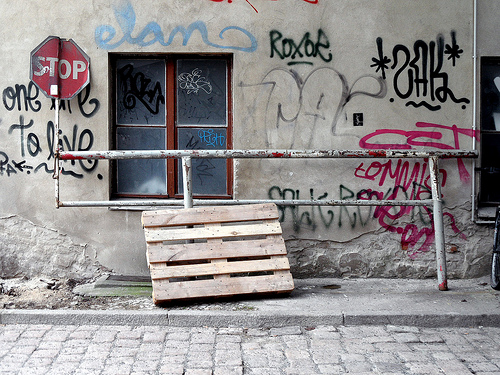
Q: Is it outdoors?
A: Yes, it is outdoors.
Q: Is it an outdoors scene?
A: Yes, it is outdoors.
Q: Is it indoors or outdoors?
A: It is outdoors.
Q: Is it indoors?
A: No, it is outdoors.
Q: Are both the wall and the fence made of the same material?
A: No, the wall is made of concrete and the fence is made of metal.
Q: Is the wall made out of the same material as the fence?
A: No, the wall is made of concrete and the fence is made of metal.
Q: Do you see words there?
A: Yes, there are words.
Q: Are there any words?
A: Yes, there are words.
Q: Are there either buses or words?
A: Yes, there are words.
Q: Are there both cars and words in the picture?
A: No, there are words but no cars.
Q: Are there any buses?
A: No, there are no buses.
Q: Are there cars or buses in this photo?
A: No, there are no buses or cars.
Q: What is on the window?
A: The words are on the window.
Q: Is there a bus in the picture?
A: No, there are no buses.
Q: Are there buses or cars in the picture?
A: No, there are no buses or cars.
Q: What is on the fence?
A: The sign is on the fence.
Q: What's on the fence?
A: The sign is on the fence.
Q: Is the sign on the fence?
A: Yes, the sign is on the fence.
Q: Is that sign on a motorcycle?
A: No, the sign is on the fence.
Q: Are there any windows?
A: Yes, there is a window.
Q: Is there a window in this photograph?
A: Yes, there is a window.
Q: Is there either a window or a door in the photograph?
A: Yes, there is a window.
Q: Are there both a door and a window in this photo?
A: No, there is a window but no doors.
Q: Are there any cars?
A: No, there are no cars.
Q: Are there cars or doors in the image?
A: No, there are no cars or doors.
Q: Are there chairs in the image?
A: No, there are no chairs.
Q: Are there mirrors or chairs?
A: No, there are no chairs or mirrors.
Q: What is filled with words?
A: The wall is filled with words.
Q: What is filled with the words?
A: The wall is filled with words.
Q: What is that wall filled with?
A: The wall is filled with words.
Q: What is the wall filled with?
A: The wall is filled with words.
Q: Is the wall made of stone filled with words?
A: Yes, the wall is filled with words.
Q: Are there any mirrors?
A: No, there are no mirrors.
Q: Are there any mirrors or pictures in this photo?
A: No, there are no mirrors or pictures.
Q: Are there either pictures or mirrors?
A: No, there are no mirrors or pictures.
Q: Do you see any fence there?
A: Yes, there is a fence.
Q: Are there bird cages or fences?
A: Yes, there is a fence.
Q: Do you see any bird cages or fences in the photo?
A: Yes, there is a fence.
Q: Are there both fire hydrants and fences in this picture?
A: No, there is a fence but no fire hydrants.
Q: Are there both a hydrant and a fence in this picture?
A: No, there is a fence but no fire hydrants.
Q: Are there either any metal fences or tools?
A: Yes, there is a metal fence.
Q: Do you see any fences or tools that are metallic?
A: Yes, the fence is metallic.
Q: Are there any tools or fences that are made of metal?
A: Yes, the fence is made of metal.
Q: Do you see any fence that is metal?
A: Yes, there is a metal fence.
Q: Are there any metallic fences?
A: Yes, there is a metal fence.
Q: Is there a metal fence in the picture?
A: Yes, there is a metal fence.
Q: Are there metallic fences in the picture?
A: Yes, there is a metal fence.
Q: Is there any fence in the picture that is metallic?
A: Yes, there is a fence that is metallic.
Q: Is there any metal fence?
A: Yes, there is a fence that is made of metal.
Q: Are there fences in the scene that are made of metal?
A: Yes, there is a fence that is made of metal.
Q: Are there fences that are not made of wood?
A: Yes, there is a fence that is made of metal.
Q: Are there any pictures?
A: No, there are no pictures.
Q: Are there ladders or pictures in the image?
A: No, there are no pictures or ladders.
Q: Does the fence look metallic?
A: Yes, the fence is metallic.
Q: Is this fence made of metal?
A: Yes, the fence is made of metal.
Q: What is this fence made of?
A: The fence is made of metal.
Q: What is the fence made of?
A: The fence is made of metal.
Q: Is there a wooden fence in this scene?
A: No, there is a fence but it is metallic.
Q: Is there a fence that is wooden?
A: No, there is a fence but it is metallic.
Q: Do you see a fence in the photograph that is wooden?
A: No, there is a fence but it is metallic.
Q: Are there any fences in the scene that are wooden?
A: No, there is a fence but it is metallic.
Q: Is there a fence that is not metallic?
A: No, there is a fence but it is metallic.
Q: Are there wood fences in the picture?
A: No, there is a fence but it is made of metal.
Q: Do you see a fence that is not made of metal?
A: No, there is a fence but it is made of metal.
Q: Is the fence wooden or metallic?
A: The fence is metallic.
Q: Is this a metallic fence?
A: Yes, this is a metallic fence.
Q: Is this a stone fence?
A: No, this is a metallic fence.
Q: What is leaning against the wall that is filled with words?
A: The fence is leaning against the wall.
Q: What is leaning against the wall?
A: The fence is leaning against the wall.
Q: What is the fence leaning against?
A: The fence is leaning against the wall.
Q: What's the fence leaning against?
A: The fence is leaning against the wall.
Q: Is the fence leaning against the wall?
A: Yes, the fence is leaning against the wall.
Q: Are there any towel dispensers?
A: No, there are no towel dispensers.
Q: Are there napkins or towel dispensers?
A: No, there are no towel dispensers or napkins.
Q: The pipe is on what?
A: The pipe is on the wall.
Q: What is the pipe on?
A: The pipe is on the wall.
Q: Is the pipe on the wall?
A: Yes, the pipe is on the wall.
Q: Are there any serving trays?
A: No, there are no serving trays.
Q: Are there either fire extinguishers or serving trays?
A: No, there are no serving trays or fire extinguishers.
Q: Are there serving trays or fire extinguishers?
A: No, there are no serving trays or fire extinguishers.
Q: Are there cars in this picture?
A: No, there are no cars.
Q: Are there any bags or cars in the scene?
A: No, there are no cars or bags.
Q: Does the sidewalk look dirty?
A: Yes, the sidewalk is dirty.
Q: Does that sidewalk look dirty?
A: Yes, the sidewalk is dirty.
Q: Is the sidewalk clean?
A: No, the sidewalk is dirty.